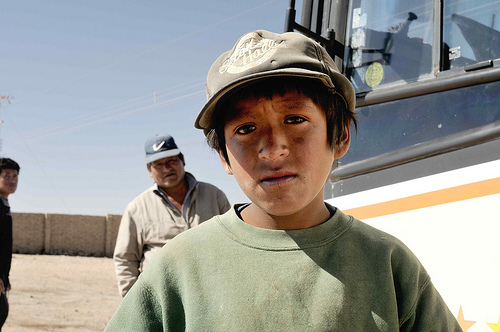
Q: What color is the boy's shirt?
A: Green.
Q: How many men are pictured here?
A: Three.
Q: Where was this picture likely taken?
A: A Bus Stop.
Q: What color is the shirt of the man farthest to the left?
A: Black.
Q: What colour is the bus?
A: Black, White and Orange.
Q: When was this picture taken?
A: Daytime.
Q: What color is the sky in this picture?
A: Blue.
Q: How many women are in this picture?
A: Zero.